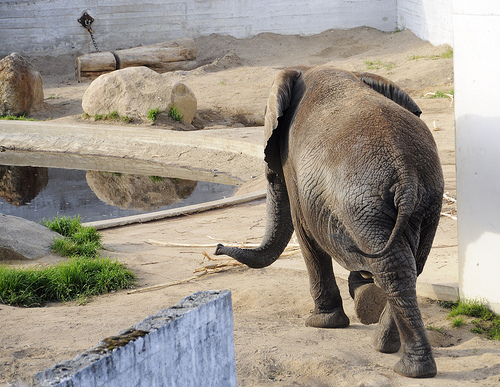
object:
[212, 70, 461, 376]
elephant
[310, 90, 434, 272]
skin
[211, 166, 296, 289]
trunk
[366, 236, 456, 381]
leg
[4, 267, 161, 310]
grass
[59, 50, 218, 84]
tree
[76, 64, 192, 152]
rock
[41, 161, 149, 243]
pond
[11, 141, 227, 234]
water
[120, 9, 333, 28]
wall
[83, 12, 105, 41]
chain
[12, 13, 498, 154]
building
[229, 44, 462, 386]
animal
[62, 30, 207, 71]
tree trunk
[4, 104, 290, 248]
pool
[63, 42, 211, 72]
log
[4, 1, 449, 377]
pen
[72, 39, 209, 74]
log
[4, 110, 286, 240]
pool